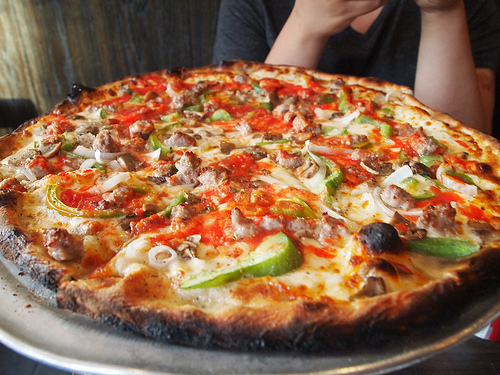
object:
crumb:
[24, 302, 33, 308]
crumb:
[11, 291, 17, 296]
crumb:
[16, 270, 26, 277]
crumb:
[16, 282, 21, 286]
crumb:
[31, 288, 53, 298]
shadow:
[0, 97, 38, 131]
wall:
[0, 1, 220, 136]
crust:
[0, 58, 500, 354]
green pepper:
[178, 233, 304, 290]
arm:
[412, 9, 488, 135]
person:
[210, 0, 498, 136]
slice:
[403, 234, 481, 259]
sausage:
[79, 126, 130, 165]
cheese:
[125, 103, 305, 237]